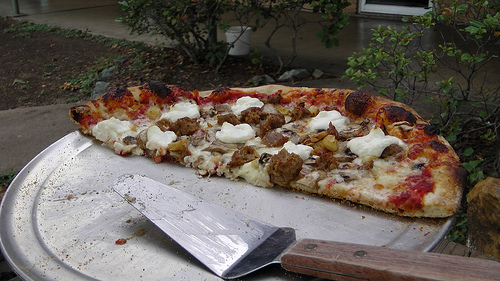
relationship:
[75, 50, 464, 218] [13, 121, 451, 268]
pizza on pizza tray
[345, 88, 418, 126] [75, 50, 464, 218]
edge on pizza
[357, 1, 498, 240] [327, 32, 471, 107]
plant in background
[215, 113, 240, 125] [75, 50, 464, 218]
meat topping on pizza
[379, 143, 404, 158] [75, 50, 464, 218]
meat topping on pizza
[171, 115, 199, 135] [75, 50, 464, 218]
meat topping on pizza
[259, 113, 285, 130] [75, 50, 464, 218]
meat topping on pizza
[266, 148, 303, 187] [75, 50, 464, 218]
meat topping on pizza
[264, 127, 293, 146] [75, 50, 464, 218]
meattopping on pizza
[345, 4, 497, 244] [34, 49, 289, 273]
bush behind pizza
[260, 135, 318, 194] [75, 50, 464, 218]
sausage on pizza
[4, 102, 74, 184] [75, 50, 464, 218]
sidewalk behind pizza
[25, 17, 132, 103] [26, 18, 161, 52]
weed growing at edge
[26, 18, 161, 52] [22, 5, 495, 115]
edge of sidewalk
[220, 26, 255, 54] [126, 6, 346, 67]
bucket behind bush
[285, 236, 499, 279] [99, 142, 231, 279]
handle on spatula.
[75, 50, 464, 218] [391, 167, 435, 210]
pizza on sauce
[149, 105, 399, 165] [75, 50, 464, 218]
white cheese melted on pizza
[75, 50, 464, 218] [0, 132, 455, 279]
pizza on a silver pan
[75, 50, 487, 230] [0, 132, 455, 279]
pizza on a silver pan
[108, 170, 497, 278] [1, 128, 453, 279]
spatula on a tray